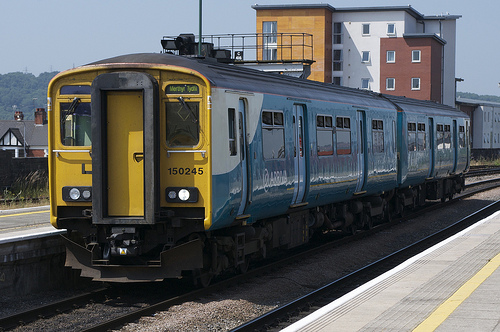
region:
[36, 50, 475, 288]
train on train tracks with yellow face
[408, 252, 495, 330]
yellow line on cement platform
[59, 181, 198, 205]
headlights on front of train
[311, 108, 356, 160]
two train windows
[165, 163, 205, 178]
numbers on front of train in black lettering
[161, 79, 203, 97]
digital window on front of train with green lettering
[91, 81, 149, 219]
yellow train door with handle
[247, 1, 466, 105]
tall building in back of train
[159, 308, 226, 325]
grey rocks and gravel on side of train track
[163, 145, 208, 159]
silver handles on front of train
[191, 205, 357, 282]
shadow cast on the track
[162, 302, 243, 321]
pebbles on the track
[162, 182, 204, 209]
white light at front of the train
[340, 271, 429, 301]
white line at edge of platform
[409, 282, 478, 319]
wide yellow line on platform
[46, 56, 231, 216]
yellow front of train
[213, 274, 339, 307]
tall blue train tracks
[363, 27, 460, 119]
smaller red building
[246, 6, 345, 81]
tall orange building in the background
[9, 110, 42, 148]
gray roof on house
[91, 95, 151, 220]
a yellow door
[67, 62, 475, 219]
a passenger train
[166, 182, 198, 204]
a light on the train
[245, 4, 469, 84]
building in the background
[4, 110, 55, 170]
a house to the left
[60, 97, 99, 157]
a window on the train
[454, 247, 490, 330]
a yellow stripe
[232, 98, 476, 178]
blue paint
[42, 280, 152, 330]
the rails are made of steel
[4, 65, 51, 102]
a hill in the background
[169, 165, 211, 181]
black numbers on front of the train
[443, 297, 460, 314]
a yellow line marking the platform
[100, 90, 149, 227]
a yellow door on the train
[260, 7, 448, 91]
a multicolored building behind the train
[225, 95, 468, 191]
a line of blue train cars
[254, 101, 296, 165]
a window in the blue train car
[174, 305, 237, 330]
gray gravel scattered between the tracks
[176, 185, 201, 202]
a lit headlight on the train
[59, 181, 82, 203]
an unlit headlight on the train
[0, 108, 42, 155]
a brick house across from the tracks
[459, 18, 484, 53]
part of the sky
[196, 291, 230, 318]
part of a ground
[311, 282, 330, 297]
edge of a rail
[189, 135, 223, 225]
edge of a train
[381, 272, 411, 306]
part of a floor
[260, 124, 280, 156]
part of a window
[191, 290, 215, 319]
part of a ground